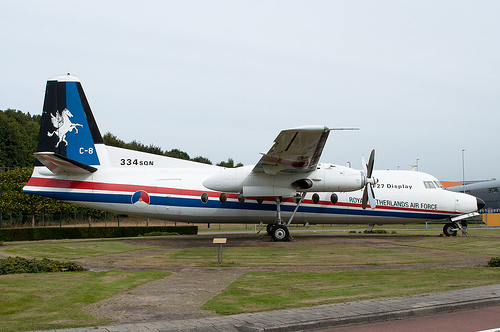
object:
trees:
[0, 109, 23, 166]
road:
[290, 305, 500, 331]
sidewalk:
[79, 268, 250, 331]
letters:
[375, 198, 381, 205]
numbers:
[120, 157, 126, 165]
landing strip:
[130, 234, 499, 241]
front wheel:
[440, 223, 461, 238]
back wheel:
[267, 224, 289, 243]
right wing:
[248, 123, 333, 176]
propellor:
[358, 148, 384, 211]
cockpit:
[420, 173, 444, 190]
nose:
[474, 196, 492, 212]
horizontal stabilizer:
[30, 150, 100, 178]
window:
[198, 193, 210, 204]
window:
[215, 192, 230, 204]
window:
[234, 192, 249, 205]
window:
[311, 190, 321, 204]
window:
[327, 191, 340, 207]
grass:
[0, 221, 499, 331]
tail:
[32, 76, 103, 169]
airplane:
[23, 70, 487, 237]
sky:
[0, 0, 500, 183]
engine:
[200, 165, 366, 200]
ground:
[0, 224, 500, 331]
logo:
[44, 105, 84, 149]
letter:
[386, 182, 392, 188]